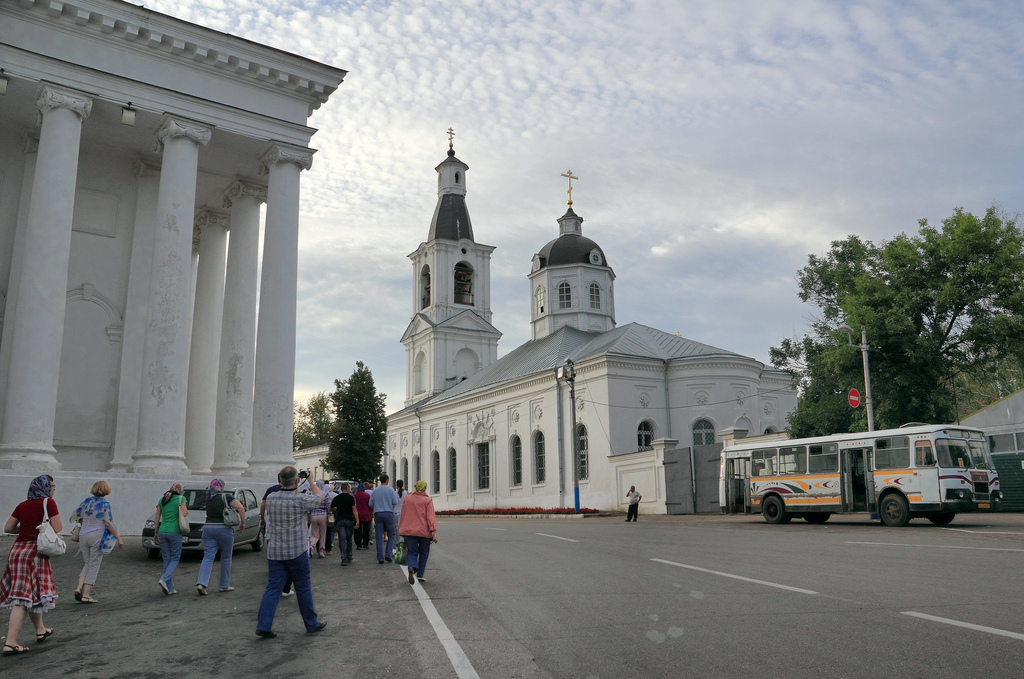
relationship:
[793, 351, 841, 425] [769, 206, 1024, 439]
leaves on leaves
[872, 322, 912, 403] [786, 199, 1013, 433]
leaves on tree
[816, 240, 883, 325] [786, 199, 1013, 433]
leaves on tree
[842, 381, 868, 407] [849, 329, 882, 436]
sign on pole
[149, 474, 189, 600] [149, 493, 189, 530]
woman in shirt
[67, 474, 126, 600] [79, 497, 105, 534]
woman in shirt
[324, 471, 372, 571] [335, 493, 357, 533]
man with shirt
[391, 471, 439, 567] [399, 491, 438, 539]
person with jacket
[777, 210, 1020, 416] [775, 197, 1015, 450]
leaves on tree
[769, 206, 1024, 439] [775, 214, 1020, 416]
leaves on tree